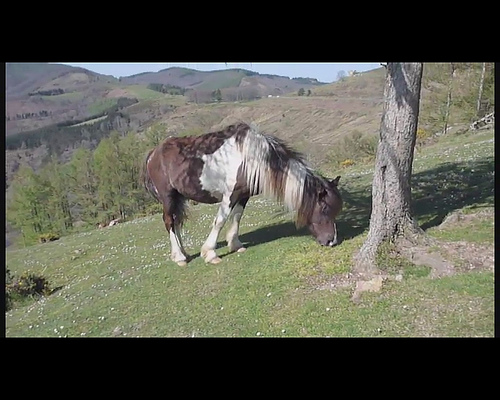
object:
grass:
[1, 133, 499, 339]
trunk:
[360, 62, 433, 264]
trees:
[147, 83, 188, 96]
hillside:
[43, 86, 187, 112]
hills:
[4, 63, 123, 144]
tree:
[352, 61, 431, 270]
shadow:
[189, 157, 496, 262]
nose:
[327, 236, 339, 245]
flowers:
[96, 242, 154, 285]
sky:
[56, 63, 384, 82]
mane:
[244, 124, 328, 232]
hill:
[5, 129, 493, 336]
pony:
[144, 123, 340, 267]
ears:
[329, 176, 343, 188]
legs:
[198, 197, 233, 262]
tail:
[139, 148, 162, 202]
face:
[312, 187, 341, 248]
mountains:
[118, 67, 328, 102]